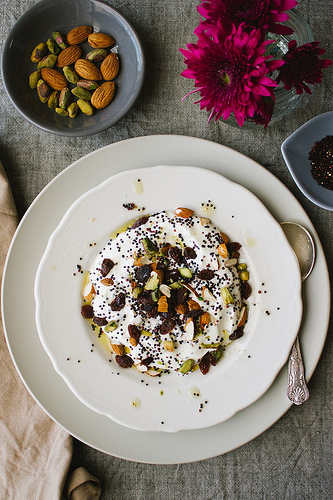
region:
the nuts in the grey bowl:
[22, 20, 128, 119]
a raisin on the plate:
[114, 352, 132, 371]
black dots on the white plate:
[253, 282, 283, 320]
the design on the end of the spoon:
[285, 347, 306, 409]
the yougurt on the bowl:
[79, 187, 262, 409]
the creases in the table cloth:
[276, 426, 328, 499]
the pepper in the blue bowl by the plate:
[301, 131, 331, 201]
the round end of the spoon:
[281, 215, 315, 285]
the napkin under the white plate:
[2, 416, 102, 499]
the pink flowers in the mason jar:
[176, 0, 332, 132]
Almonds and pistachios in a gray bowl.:
[1, 0, 145, 137]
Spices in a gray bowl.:
[281, 109, 332, 211]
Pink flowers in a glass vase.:
[179, 0, 332, 129]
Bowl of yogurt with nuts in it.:
[34, 165, 302, 431]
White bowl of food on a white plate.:
[2, 133, 331, 465]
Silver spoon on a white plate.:
[278, 220, 316, 405]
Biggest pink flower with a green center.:
[179, 24, 285, 125]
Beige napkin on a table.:
[0, 161, 72, 499]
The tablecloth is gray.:
[0, 0, 331, 499]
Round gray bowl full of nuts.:
[1, 0, 144, 136]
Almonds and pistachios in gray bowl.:
[0, 2, 150, 139]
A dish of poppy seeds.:
[281, 107, 332, 214]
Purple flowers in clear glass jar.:
[184, 0, 330, 120]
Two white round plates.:
[0, 131, 331, 469]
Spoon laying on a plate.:
[273, 214, 314, 409]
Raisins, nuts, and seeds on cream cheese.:
[91, 214, 237, 374]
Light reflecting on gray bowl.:
[114, 0, 151, 114]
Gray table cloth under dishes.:
[0, 3, 318, 497]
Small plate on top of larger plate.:
[3, 124, 329, 473]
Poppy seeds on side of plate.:
[134, 379, 231, 432]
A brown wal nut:
[87, 80, 117, 109]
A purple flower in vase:
[181, 13, 269, 130]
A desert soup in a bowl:
[80, 210, 255, 376]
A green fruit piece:
[178, 359, 193, 374]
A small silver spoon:
[271, 221, 317, 407]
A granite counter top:
[257, 440, 332, 498]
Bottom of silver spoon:
[284, 373, 311, 408]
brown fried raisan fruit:
[110, 288, 125, 312]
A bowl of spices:
[308, 132, 331, 191]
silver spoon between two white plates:
[3, 133, 327, 466]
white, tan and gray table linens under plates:
[3, 373, 325, 492]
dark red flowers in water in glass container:
[179, 3, 328, 124]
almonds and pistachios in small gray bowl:
[2, 0, 137, 130]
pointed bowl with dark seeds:
[275, 108, 322, 203]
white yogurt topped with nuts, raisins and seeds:
[81, 209, 241, 360]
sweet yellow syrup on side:
[75, 213, 129, 342]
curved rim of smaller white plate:
[33, 161, 304, 431]